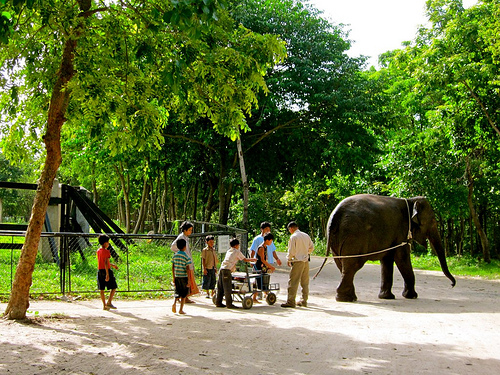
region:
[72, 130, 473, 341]
An elephant is pulling some children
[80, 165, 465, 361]
An elephant is entertaining some kids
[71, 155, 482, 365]
An elephant is wearing a harness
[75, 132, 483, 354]
An elephant is walking around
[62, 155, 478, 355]
An elephant is with its handler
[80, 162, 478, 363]
Kids are playing in a park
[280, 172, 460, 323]
A man is standing next to an elephant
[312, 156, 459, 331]
An elephant is standing on a road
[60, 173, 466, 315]
Elephant is enjoying some attention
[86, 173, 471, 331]
Kids are playing with an elephant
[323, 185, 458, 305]
an elephant pulling a wagon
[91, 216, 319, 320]
group walking behind an elephant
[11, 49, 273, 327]
tree with bright green leaves that is leaning slightly to the right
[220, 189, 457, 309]
an elephant that is working outside pulling a cart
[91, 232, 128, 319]
young boy walking outside on sand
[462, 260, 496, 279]
bright green grass on the side of the road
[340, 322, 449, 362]
sand or dirt walkway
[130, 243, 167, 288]
chain link fence going around a grassy park-like area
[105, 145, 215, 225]
a bunch of tall, skinny trees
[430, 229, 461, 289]
an elephant's trunk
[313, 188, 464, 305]
elephant in front of group of people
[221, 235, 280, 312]
boy pushing metal wagon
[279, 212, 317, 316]
man in white shirt and khakis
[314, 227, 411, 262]
white string behind elephant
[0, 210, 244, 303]
chain link fence surrounds grass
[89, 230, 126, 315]
one boy lagging behind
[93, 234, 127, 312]
boy in orange shirt and black shorts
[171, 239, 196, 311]
boy in blue and white striped shirt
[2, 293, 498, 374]
shadow of tree on ground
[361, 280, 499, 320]
shadow of elephant on ground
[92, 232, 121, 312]
Boy is wearing shorts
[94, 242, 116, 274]
Boy is wearing a red shirt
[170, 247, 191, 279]
Boy is wearing a green and white striped shirt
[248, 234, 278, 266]
Boy is wearing a blue shirt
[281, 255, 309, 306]
Man is wearing pants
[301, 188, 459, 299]
Elephant is being held by rope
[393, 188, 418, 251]
Elephant has rope around its neck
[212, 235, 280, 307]
Boy is pushing a cart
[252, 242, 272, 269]
Boy is wearing a tank top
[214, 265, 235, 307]
Boy is wearing pants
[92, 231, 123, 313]
Little boy walking at the back of the group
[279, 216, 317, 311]
Man talking to goup of kids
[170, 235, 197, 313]
Little boy wearing a green and yellow shirt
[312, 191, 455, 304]
Elephant walking in front of the group of boys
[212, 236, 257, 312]
Little boy wearing beige shirt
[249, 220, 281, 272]
Kid wearing a blue shirt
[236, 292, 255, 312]
Right rear wheel of wagon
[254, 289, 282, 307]
Front wheel of wagon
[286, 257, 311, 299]
Man wearing tan pants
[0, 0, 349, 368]
Tall tree on road